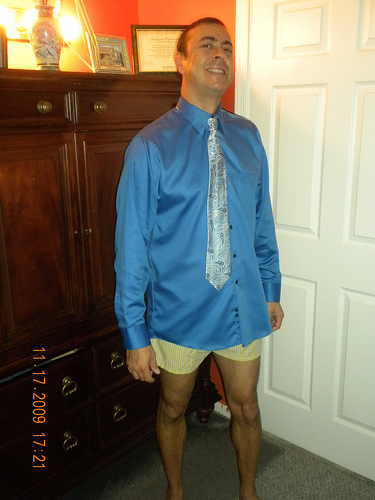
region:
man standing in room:
[81, 19, 294, 495]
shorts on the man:
[149, 336, 267, 369]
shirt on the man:
[112, 98, 275, 342]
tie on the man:
[190, 113, 238, 290]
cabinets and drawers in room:
[4, 62, 211, 468]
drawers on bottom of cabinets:
[14, 340, 217, 487]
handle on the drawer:
[55, 377, 80, 398]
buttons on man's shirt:
[222, 223, 249, 334]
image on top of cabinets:
[87, 30, 129, 73]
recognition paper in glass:
[128, 28, 191, 73]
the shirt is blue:
[158, 140, 193, 173]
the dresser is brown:
[15, 166, 51, 203]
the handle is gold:
[59, 378, 81, 398]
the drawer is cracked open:
[16, 346, 71, 374]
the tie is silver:
[210, 162, 228, 201]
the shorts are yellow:
[160, 343, 181, 367]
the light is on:
[56, 8, 92, 50]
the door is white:
[268, 21, 326, 60]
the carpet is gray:
[286, 461, 321, 487]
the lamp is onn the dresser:
[35, 35, 67, 77]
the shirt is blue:
[98, 87, 297, 346]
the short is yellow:
[117, 311, 264, 406]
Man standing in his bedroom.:
[11, 6, 365, 488]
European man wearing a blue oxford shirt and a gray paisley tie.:
[95, 16, 325, 332]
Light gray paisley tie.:
[191, 112, 243, 297]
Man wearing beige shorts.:
[145, 302, 275, 382]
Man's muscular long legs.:
[154, 343, 282, 491]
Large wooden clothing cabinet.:
[8, 59, 218, 489]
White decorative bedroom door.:
[234, 5, 374, 491]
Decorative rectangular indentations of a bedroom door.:
[258, 9, 370, 449]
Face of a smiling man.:
[164, 11, 245, 103]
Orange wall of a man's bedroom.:
[0, 2, 246, 152]